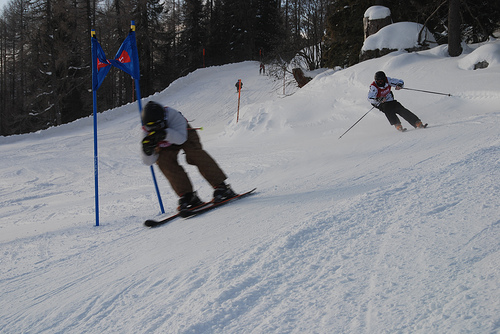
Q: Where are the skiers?
A: On the hillside.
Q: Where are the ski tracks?
A: On the snow.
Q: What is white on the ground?
A: Snow.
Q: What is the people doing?
A: Skiing.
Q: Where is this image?
A: A ski slope.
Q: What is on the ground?
A: Snow.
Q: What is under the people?
A: Skies.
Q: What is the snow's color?
A: White.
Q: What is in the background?
A: Trees.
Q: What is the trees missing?
A: Leaves.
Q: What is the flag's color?
A: Blue.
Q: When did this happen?
A: During the day time.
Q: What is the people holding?
A: Ski poles.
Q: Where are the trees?
A: Top of the slope.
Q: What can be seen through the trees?
A: Sky.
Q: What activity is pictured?
A: Skiing.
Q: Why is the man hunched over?
A: For speed.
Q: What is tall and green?
A: Trees.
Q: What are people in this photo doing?
A: Skiing.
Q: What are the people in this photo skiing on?
A: Skis.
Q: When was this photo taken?
A: Daytime.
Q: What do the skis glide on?
A: Snow.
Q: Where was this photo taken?
A: Ski slope.